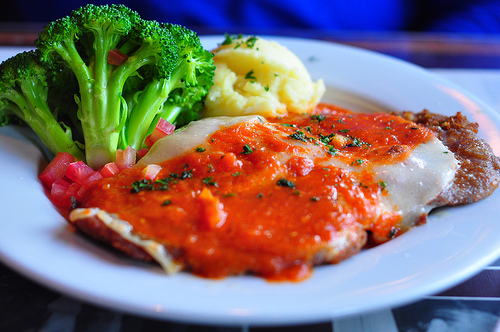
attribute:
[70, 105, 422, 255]
sauce — red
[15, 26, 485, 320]
plate — round, white, circular, food, ceramic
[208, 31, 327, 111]
potatoes — mound, yellowish, mashed, white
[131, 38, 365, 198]
seasoning — green, sprinkled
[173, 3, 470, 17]
shirt — blue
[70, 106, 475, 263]
sauce — red, tomato based, meat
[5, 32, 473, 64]
edge — wood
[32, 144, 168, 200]
radish — red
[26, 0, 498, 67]
shirt — blue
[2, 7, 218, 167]
broccoli — green colored, green, steamed, bunch, cooked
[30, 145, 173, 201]
tomatoes — sliced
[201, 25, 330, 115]
food — yellow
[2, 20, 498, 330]
plate — white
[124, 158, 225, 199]
herb — green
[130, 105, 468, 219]
cheese — melted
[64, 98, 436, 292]
sauce — red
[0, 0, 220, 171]
food — green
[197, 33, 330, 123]
food — white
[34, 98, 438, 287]
food — red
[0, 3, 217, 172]
broccoli head — green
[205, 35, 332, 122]
potatoes serving — small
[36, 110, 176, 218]
tomatoes — finely diced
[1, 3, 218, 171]
vegetables — green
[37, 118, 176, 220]
vegetables — red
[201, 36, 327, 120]
vegetables — white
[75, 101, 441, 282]
sauce — red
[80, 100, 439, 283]
pasta sauce — red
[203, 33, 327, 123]
potatoes — yellow, mashed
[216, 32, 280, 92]
onions — green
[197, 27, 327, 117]
potatoes — mashed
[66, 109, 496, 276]
meat — brown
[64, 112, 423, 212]
toppings — green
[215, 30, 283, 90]
toppings — green